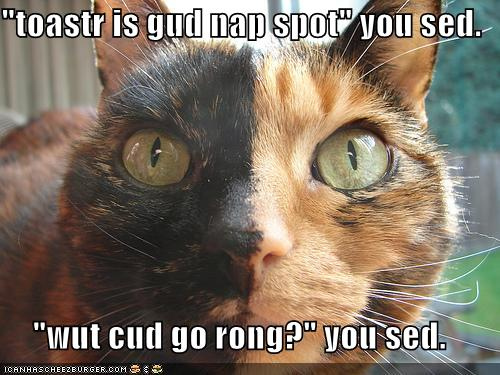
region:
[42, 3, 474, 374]
close up of a cat's face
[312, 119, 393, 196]
large green eye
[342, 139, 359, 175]
black slit on the eyeball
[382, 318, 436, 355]
said spelled incorrectly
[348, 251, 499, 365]
long white whiskers coming off the face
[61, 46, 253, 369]
half of the face is black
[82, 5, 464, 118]
two pointy ears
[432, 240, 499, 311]
field of green grass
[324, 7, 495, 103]
long white hairs on the top of the head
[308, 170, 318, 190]
black speck in the corner of the eye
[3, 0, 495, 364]
A cat is in the picture.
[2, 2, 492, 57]
The picture has words on it.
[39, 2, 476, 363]
The cat is orange, white and black.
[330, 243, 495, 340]
The cat has white whiskers.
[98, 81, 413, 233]
The cat has green eyes.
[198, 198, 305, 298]
The cat has a pink and black nose.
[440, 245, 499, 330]
Grass can be seen in the background.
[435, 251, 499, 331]
The grass is green.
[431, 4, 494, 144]
Trees can be seen in the background.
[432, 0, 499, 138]
The trees are green.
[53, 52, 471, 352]
A calico cats head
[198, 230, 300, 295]
A cats nose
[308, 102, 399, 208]
A cats left eye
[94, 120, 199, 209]
A cats right eye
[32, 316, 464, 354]
Writing across the bottom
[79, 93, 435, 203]
A couple of cat eyes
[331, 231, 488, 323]
White cat whiskers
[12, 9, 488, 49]
Writing above the cats head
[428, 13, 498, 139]
Green trees behind the cat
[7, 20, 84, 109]
A wall behind the cat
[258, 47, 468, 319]
light colored half of cat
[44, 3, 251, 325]
dark colored half of cat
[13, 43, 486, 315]
cat with interesting color pattern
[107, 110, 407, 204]
parti-colored cat's eyes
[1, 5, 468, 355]
misspelled meme writing as if cat wrote it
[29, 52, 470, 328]
black and orange cat face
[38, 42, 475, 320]
two faced feline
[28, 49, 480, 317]
feline displaying Janus coloring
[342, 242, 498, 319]
whiskers on orange fur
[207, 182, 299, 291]
cat nose in two colors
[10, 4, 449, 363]
the cat is brown and black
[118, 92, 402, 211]
cat's eyes are yellow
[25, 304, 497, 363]
the letters are white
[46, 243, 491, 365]
cat's whiskers are white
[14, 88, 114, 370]
cat's back is orange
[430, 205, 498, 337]
grass in the background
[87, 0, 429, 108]
cat's ears pointed upwards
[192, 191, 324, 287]
cat's nose is 2 different colors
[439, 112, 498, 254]
the fence is brown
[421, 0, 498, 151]
trees behind the fence